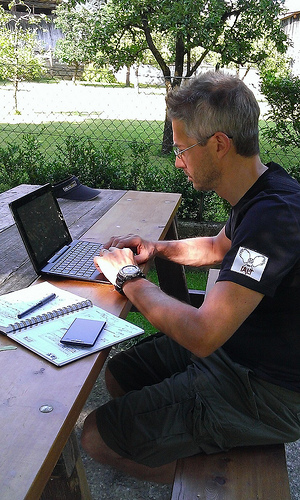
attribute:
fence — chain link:
[0, 63, 298, 222]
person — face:
[121, 77, 282, 355]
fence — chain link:
[6, 54, 171, 179]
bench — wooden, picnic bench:
[2, 180, 182, 498]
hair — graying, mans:
[194, 80, 242, 129]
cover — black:
[14, 304, 146, 366]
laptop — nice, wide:
[9, 179, 128, 278]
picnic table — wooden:
[1, 181, 183, 495]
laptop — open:
[7, 180, 90, 279]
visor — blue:
[43, 167, 104, 204]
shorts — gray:
[88, 319, 297, 463]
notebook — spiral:
[0, 280, 145, 369]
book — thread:
[0, 279, 144, 365]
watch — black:
[105, 250, 148, 298]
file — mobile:
[5, 278, 153, 362]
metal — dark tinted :
[114, 277, 123, 287]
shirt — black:
[204, 212, 286, 397]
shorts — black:
[105, 346, 269, 442]